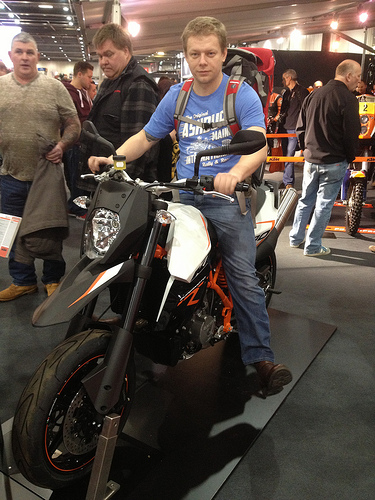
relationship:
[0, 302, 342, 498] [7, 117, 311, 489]
stand holding motorcycle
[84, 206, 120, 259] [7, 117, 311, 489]
light on motorcycle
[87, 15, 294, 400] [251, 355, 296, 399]
man wearing boot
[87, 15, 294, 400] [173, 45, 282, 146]
man wearing backpack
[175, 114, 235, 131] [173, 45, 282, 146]
grey strap on backpack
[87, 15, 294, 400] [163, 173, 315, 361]
man wearing jeans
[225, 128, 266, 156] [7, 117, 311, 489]
mirror on motorcycle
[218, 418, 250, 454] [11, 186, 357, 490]
shadow on floor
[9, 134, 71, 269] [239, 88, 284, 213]
coat in hand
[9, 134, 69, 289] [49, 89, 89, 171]
coat in hand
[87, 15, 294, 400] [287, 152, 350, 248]
man wearing jeans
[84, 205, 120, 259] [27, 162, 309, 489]
light in front of motorcycle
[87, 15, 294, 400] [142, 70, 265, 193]
man wearing shirt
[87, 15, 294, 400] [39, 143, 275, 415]
man on motorcycle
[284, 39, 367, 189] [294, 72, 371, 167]
man wearing coat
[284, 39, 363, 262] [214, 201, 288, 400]
man wearing jeans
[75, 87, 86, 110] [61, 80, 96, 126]
string on hoodie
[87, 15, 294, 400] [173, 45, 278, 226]
man with backpack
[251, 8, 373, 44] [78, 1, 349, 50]
lights on ceiling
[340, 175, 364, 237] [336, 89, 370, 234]
tire on bike